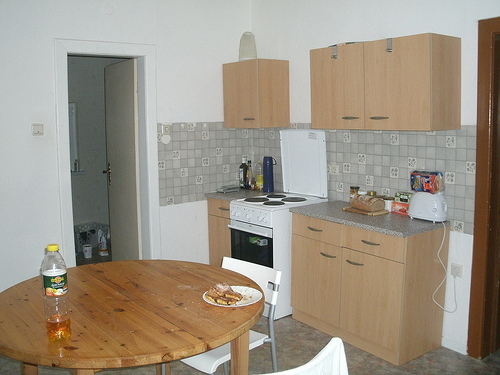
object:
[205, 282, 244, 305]
food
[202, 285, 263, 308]
plate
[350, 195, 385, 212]
bread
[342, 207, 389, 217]
board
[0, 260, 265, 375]
table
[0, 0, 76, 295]
wall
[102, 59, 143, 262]
door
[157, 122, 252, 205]
tiles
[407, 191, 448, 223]
toaster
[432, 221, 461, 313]
cord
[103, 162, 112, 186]
doorknob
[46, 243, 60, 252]
top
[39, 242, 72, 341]
bottle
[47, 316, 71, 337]
liquid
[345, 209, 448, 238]
counter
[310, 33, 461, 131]
cabinets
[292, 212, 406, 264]
drawers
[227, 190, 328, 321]
stove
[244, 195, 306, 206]
burners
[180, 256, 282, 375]
chair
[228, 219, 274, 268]
oven door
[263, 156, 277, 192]
thermos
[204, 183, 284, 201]
counter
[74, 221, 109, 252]
basket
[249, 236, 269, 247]
box